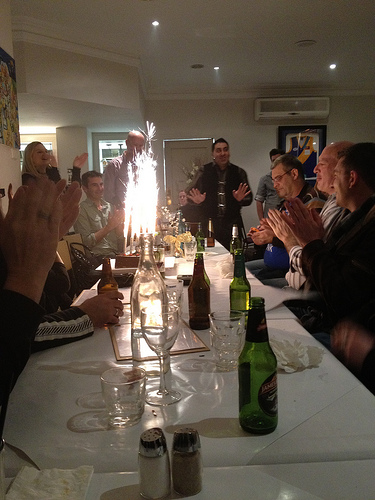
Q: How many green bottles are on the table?
A: Five.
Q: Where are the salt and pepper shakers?
A: On the first table.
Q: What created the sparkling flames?
A: Candles.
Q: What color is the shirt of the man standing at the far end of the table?
A: Black.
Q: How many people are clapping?
A: Four.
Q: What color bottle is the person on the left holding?
A: Brown.